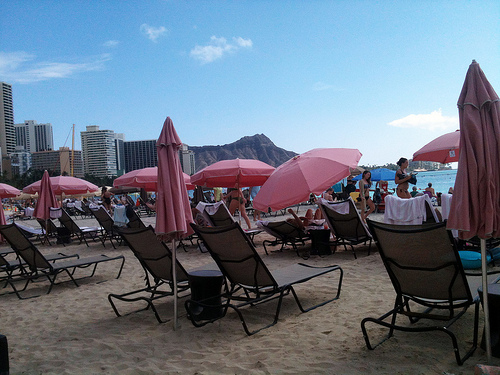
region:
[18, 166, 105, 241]
The umbrella is open.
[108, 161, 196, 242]
The umbrella is open.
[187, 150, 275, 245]
The umbrella is open.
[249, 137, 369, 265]
The umbrella is open.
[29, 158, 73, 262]
The umbrella is closed.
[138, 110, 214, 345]
The umbrella is closed.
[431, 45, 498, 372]
The umbrella is closed.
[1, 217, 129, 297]
The chaise lounge is vacant.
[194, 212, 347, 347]
The chaise lounge is vacant.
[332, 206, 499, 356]
The chaise lounge is vacant.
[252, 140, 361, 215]
Opened red umbrella slightly tilted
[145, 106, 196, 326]
Closed red umbrella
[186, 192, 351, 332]
Lounge chair sittting in the sand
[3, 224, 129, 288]
Empty lounge chair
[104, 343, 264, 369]
Footprints in the sand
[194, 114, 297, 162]
Mountain in the distance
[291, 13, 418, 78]
Cloudless blue sky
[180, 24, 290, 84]
Light, white clouds in a clear blue sky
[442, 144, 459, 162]
Number tag on a red umbrella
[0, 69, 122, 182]
Tall buildings in the background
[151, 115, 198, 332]
closed umbrella between two chairs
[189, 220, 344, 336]
brown lounge chair on the beach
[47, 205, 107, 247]
chair with close umbrella with towel on the back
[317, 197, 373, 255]
chair with towel on the back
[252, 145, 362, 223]
open umbrella with someone lying under it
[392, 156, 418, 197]
a woman with her hair in a bun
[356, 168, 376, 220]
woman walking with her hair down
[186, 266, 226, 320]
container between two chairs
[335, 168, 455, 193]
blue ocean water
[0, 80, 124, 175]
tall buildings in the background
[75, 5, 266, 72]
small white clouds in the sky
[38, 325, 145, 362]
sand on the ground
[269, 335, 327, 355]
foot prints in the sand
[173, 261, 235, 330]
small black table on the sand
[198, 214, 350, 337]
tall black lounge chair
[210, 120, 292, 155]
majestic mountain range in the distance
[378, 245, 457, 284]
black frame on chair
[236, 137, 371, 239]
wide pink umbrella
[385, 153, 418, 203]
woman walking on sand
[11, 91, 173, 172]
tall buildings in the distance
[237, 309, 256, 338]
[part of a stand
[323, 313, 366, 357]
part of a beach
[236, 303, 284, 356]
part of a stand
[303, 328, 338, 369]
part of a beach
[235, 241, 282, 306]
part of a chair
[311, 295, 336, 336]
part of a beach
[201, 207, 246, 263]
part of a chair